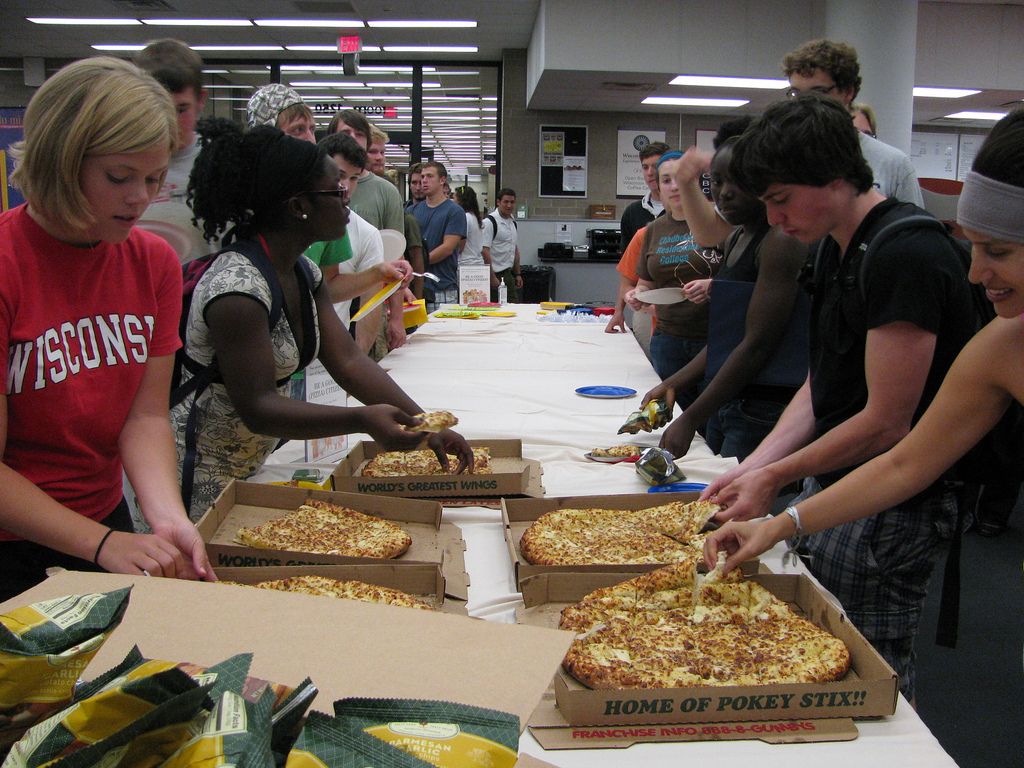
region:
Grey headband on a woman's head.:
[956, 168, 1021, 248]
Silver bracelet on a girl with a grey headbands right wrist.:
[782, 504, 803, 568]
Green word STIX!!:
[795, 690, 869, 709]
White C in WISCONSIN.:
[60, 321, 81, 375]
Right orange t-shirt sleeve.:
[611, 225, 649, 287]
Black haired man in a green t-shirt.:
[307, 131, 413, 356]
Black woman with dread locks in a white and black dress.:
[121, 115, 477, 530]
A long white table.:
[168, 298, 957, 764]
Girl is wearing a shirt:
[0, 193, 193, 542]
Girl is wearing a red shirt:
[1, 187, 205, 542]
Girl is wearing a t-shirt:
[0, 190, 193, 555]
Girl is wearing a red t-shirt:
[2, 185, 198, 556]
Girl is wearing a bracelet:
[84, 514, 126, 576]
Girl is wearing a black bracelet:
[84, 514, 122, 575]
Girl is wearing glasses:
[279, 171, 355, 210]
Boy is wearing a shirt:
[770, 184, 995, 516]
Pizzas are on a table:
[187, 400, 874, 726]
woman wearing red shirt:
[20, 64, 210, 611]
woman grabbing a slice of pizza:
[16, 56, 219, 575]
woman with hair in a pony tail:
[181, 101, 385, 494]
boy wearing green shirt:
[253, 85, 389, 367]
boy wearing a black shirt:
[737, 94, 972, 658]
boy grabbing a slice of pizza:
[722, 98, 958, 629]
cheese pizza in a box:
[535, 543, 889, 733]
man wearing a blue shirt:
[403, 157, 480, 298]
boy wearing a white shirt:
[484, 170, 538, 307]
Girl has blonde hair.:
[29, 70, 175, 255]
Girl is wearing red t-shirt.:
[6, 206, 169, 521]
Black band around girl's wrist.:
[79, 519, 134, 573]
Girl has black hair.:
[202, 126, 338, 245]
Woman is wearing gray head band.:
[950, 162, 1020, 239]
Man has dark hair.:
[730, 91, 889, 189]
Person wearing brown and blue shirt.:
[647, 206, 711, 321]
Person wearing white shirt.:
[483, 205, 522, 264]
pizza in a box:
[314, 514, 397, 581]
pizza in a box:
[361, 392, 526, 507]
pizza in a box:
[231, 553, 469, 677]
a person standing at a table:
[206, 130, 385, 437]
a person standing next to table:
[753, 181, 934, 467]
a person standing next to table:
[949, 149, 1020, 268]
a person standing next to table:
[746, 205, 1013, 465]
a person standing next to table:
[683, 203, 823, 441]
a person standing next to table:
[626, 145, 688, 259]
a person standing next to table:
[215, 143, 390, 602]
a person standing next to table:
[453, 167, 529, 348]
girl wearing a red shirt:
[8, 47, 223, 591]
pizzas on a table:
[184, 419, 911, 749]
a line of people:
[7, 31, 533, 582]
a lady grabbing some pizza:
[696, 102, 1019, 728]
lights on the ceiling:
[11, 6, 506, 70]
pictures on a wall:
[526, 113, 676, 213]